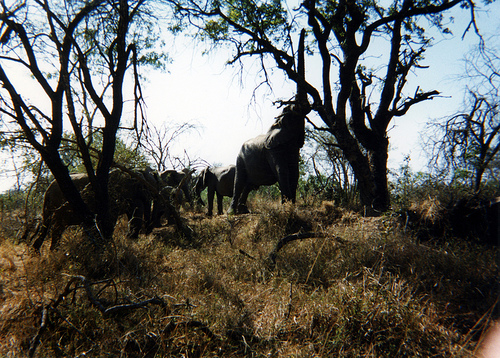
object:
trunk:
[228, 30, 309, 215]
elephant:
[226, 28, 311, 214]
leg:
[225, 164, 260, 216]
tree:
[261, 30, 428, 215]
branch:
[223, 12, 420, 94]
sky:
[163, 49, 208, 117]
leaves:
[232, 6, 306, 58]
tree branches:
[21, 195, 342, 345]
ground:
[77, 159, 442, 310]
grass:
[185, 199, 354, 289]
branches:
[182, 0, 399, 79]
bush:
[331, 165, 464, 246]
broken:
[352, 62, 441, 149]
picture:
[0, 0, 497, 358]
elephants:
[0, 21, 358, 257]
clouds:
[139, 44, 258, 122]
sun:
[175, 45, 253, 134]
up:
[276, 21, 316, 146]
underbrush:
[285, 165, 449, 278]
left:
[86, 128, 263, 245]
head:
[268, 84, 313, 153]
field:
[42, 210, 410, 290]